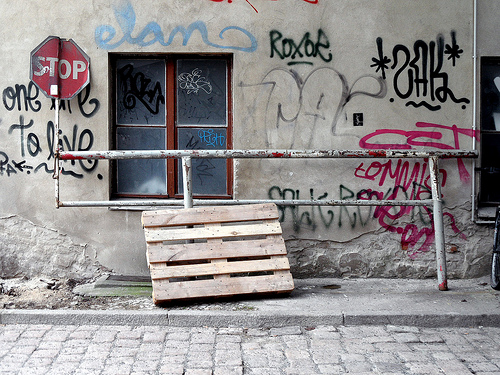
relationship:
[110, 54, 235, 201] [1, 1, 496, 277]
window on wall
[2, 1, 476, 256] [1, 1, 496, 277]
words on wall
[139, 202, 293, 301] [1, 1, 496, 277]
wood leaning against wall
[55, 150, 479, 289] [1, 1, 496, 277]
fence leans on wall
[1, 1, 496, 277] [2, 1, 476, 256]
wall has graffiti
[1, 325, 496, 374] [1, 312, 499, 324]
street near curb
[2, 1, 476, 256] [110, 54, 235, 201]
graffiti near window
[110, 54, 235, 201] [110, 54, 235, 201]
window has window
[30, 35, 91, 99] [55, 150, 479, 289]
sign on fence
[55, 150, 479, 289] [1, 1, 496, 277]
fence leans on building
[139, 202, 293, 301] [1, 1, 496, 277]
wood in front of wall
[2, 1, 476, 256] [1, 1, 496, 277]
graffiti on wall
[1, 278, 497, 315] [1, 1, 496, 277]
sidewalk in front of wall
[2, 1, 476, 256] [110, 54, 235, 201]
graffiti on window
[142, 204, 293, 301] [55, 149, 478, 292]
pallet against gate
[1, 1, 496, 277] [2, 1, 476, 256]
wall filled with graffiti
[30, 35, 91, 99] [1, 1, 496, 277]
sign on wall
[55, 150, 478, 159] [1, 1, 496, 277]
bar leans against wall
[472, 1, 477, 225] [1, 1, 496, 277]
pipe on wall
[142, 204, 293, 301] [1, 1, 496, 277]
pallet leans against wall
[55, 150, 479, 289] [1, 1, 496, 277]
fence leaning against wall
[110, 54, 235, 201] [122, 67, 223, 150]
window has graffiti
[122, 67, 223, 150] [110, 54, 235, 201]
graffiti on window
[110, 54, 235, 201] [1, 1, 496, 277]
window in wall